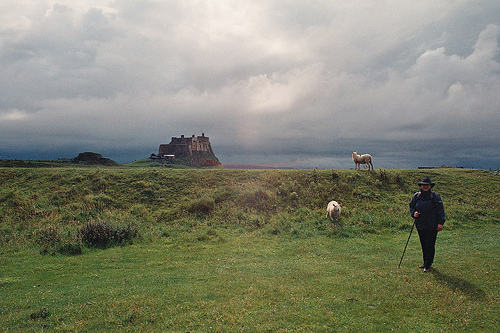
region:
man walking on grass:
[392, 173, 453, 266]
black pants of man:
[421, 226, 444, 263]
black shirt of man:
[399, 189, 447, 225]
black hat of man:
[415, 177, 433, 185]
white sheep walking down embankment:
[313, 190, 348, 230]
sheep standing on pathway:
[348, 145, 381, 170]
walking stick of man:
[393, 215, 418, 259]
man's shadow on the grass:
[418, 259, 486, 304]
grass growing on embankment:
[6, 173, 476, 240]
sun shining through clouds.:
[189, 10, 309, 138]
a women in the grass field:
[393, 171, 453, 277]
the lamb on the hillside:
[316, 194, 350, 231]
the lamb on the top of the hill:
[348, 147, 374, 172]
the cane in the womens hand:
[397, 207, 422, 268]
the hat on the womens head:
[414, 174, 441, 197]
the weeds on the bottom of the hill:
[75, 218, 142, 252]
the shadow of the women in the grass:
[429, 264, 489, 312]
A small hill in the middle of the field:
[59, 144, 116, 171]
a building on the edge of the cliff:
[151, 127, 213, 161]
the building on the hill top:
[157, 129, 212, 157]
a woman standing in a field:
[393, 175, 448, 273]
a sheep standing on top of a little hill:
[346, 148, 375, 168]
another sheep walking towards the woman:
[325, 198, 344, 221]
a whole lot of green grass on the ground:
[18, 240, 497, 328]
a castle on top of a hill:
[153, 133, 218, 169]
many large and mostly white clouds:
[2, 5, 499, 150]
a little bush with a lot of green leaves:
[70, 215, 135, 250]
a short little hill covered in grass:
[7, 168, 498, 240]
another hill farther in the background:
[72, 151, 114, 165]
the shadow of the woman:
[430, 266, 487, 308]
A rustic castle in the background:
[151, 130, 230, 169]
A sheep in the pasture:
[321, 190, 346, 231]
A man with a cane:
[390, 175, 446, 290]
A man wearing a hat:
[414, 170, 441, 197]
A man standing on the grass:
[406, 172, 453, 274]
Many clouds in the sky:
[269, 50, 459, 122]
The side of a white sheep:
[340, 144, 391, 181]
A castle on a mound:
[138, 120, 242, 170]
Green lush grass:
[67, 178, 276, 260]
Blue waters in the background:
[380, 133, 499, 168]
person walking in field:
[396, 171, 445, 264]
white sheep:
[312, 192, 353, 238]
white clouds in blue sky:
[25, 14, 77, 71]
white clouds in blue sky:
[30, 57, 106, 117]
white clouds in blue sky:
[123, 39, 176, 72]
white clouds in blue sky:
[139, 25, 189, 85]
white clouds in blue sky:
[220, 73, 278, 122]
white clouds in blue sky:
[282, 14, 326, 53]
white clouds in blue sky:
[319, 73, 361, 125]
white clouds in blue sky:
[344, 54, 431, 127]